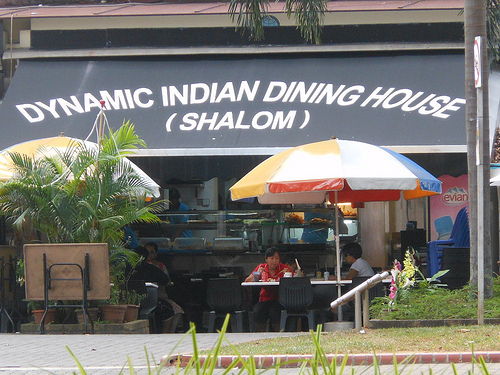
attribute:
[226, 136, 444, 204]
umbrella — multicolored, open, red, colorful, yellow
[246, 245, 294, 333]
woman — person, eating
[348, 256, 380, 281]
top — white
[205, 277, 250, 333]
chair — black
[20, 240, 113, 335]
table — up, folded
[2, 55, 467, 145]
sign — black, worded, lettered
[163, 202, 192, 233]
uniform — blue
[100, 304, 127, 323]
pot — clay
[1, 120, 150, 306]
tree — green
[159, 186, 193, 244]
worker — inside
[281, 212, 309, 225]
food — inside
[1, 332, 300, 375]
sidewalk — forward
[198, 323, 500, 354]
grass — long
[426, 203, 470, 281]
seat — blue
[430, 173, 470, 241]
poster — behind